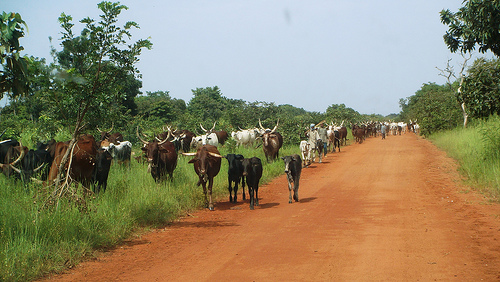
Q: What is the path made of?
A: Dirt.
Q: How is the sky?
A: Clear and blue.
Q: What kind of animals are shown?
A: Cattle.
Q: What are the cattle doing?
A: Walking.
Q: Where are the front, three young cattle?
A: In the path.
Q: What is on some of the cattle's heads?
A: Horns.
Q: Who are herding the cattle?
A: Some farmers.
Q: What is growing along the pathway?
A: Grass and trees.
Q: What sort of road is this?
A: A red clay road.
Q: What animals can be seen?
A: Cattle.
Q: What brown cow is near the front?
A: The one walking half on and half off the road.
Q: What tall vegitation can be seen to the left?
A: A group of trees.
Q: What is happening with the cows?
A: They are part of a cattle drive.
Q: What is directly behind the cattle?
A: A line of bushes.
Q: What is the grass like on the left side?
A: Long and green.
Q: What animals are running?
A: Bulls.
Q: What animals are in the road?
A: Bulls.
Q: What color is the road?
A: Brown.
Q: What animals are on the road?
A: Cows.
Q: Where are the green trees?
A: Sides of the road.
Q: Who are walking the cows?
A: Men.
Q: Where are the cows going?
A: Down the road.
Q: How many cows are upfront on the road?
A: Four.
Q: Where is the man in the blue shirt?
A: On the road.